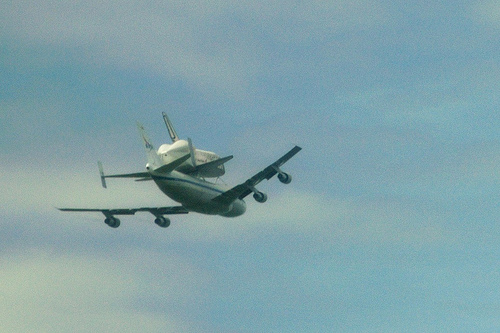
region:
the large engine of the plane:
[103, 211, 122, 228]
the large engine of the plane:
[152, 211, 169, 228]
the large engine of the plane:
[247, 184, 266, 204]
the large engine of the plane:
[269, 165, 291, 182]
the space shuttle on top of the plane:
[148, 110, 225, 178]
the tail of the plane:
[91, 161, 146, 191]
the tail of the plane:
[161, 139, 203, 174]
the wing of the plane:
[56, 205, 189, 217]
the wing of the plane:
[220, 141, 302, 206]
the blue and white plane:
[51, 121, 304, 233]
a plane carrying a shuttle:
[50, 103, 310, 235]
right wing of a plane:
[226, 146, 305, 196]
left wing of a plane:
[54, 203, 179, 220]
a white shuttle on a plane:
[154, 110, 242, 170]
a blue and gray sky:
[339, 13, 491, 330]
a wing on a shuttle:
[196, 152, 236, 174]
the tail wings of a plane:
[132, 131, 187, 185]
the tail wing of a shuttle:
[160, 111, 182, 143]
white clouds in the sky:
[4, 268, 125, 325]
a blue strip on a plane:
[154, 174, 222, 194]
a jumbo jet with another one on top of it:
[54, 110, 304, 232]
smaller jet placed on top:
[134, 111, 231, 176]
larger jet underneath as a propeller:
[57, 145, 312, 229]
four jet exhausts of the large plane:
[101, 167, 293, 232]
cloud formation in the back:
[7, 148, 430, 236]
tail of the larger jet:
[131, 117, 166, 169]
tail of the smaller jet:
[160, 104, 180, 147]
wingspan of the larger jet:
[51, 144, 303, 212]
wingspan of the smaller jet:
[136, 151, 236, 183]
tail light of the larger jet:
[144, 162, 149, 170]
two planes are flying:
[62, 88, 329, 259]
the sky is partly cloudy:
[97, 21, 458, 262]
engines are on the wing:
[220, 153, 307, 230]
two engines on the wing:
[208, 149, 311, 224]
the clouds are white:
[2, 98, 253, 310]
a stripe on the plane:
[145, 168, 219, 198]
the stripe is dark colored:
[145, 167, 213, 197]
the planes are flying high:
[50, 80, 320, 250]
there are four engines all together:
[75, 167, 341, 237]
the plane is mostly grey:
[122, 157, 235, 220]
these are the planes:
[62, 120, 319, 249]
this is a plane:
[242, 145, 312, 197]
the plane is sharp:
[260, 140, 309, 199]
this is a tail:
[98, 148, 193, 187]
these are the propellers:
[261, 165, 294, 200]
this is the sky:
[301, 32, 413, 107]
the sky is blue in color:
[265, 6, 432, 134]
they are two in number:
[85, 132, 262, 226]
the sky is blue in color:
[326, 225, 453, 330]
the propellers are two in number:
[248, 172, 294, 205]